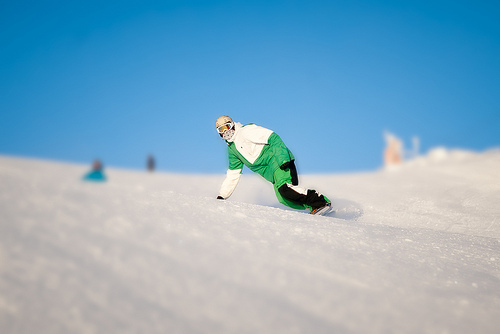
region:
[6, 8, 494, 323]
people skiing on a sunny day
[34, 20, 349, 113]
clear and bright blue sky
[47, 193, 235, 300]
bright white snow out of focus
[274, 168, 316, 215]
black white and green pants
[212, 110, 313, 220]
man wearing white, green, and black winter clothes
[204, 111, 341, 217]
Man riding snowboard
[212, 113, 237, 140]
Man wearing white ski goggles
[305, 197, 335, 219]
snowboard cutting through snow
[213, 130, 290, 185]
green and white ski jacket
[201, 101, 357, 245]
man riding down a snowy mountain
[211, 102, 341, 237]
A person snowboarding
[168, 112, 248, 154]
Gold colored helmet worn by snowboarder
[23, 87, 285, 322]
Snow hill with 3 people on it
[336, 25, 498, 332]
Snow hill with blue sky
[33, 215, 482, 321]
Tightly packed snow on a hill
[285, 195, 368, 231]
Snowboard on snow hill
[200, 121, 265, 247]
Snowboarder touching snow for balance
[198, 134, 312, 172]
Snowboarder's green jacket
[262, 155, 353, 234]
Snowboarder's green pants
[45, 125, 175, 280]
Two people on a snow hill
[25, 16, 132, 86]
a clear blue sky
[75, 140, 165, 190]
out-of-focus figures in the snow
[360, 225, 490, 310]
patch of powdery snow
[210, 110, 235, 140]
snow boarder's gold helmet and goggles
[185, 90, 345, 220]
man making his way down the slope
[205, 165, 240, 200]
man's arm extended for balance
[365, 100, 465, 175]
figures in the snow against the sky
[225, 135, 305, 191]
green, white, and black outfit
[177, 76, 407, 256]
snow boarder leans into his ride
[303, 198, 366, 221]
snow board along the white surface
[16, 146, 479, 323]
White fluffy clean snow.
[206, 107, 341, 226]
Green and while outfit for the snow.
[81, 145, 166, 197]
People in the distance.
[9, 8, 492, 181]
Crisp blue sky without clouds.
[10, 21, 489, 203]
No clouds in sight in the sky.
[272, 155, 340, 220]
Person dressed in black and white pants.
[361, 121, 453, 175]
Unidentified objects in the distance.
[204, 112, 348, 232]
Person leaning to the right.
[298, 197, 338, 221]
Gray and orange winter shoes.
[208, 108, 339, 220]
Gold helmet with guard for protection.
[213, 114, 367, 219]
snow boarder is wearing white and green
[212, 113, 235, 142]
snow boarder is wearing goggles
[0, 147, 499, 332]
the snow is white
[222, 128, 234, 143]
snow boarder has on bandana over mouth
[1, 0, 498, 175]
the sky blue and clear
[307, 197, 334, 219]
the snowboard is white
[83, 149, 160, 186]
people are seen in background on hill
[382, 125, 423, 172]
people standing on hill watching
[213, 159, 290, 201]
snow boarder is wearing black gloves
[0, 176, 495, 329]
snow has several tracks in it